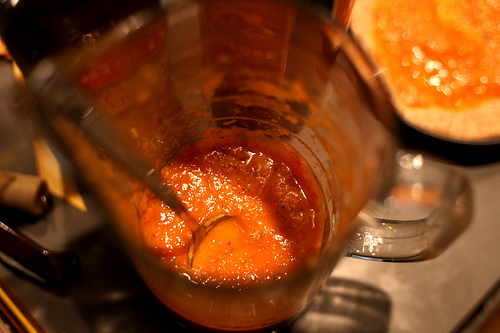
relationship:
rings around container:
[127, 81, 347, 293] [55, 22, 409, 323]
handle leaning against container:
[18, 57, 215, 232] [38, 24, 352, 324]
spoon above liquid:
[62, 105, 244, 262] [165, 153, 306, 263]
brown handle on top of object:
[1, 170, 48, 215] [2, 193, 111, 316]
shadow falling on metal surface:
[294, 279, 390, 331] [292, 146, 497, 331]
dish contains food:
[134, 89, 365, 257] [132, 148, 312, 266]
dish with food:
[134, 89, 365, 257] [132, 148, 312, 266]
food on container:
[361, 3, 499, 128] [44, 30, 462, 315]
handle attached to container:
[342, 148, 475, 265] [18, 2, 436, 328]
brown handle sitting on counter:
[1, 170, 48, 215] [19, 179, 487, 331]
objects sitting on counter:
[40, 137, 82, 208] [19, 179, 487, 331]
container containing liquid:
[22, 0, 475, 333] [113, 133, 328, 303]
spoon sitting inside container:
[40, 76, 237, 268] [22, 0, 475, 333]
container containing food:
[22, 0, 475, 333] [132, 137, 328, 288]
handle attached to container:
[342, 147, 477, 266] [22, 0, 475, 333]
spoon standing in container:
[40, 76, 237, 268] [22, 0, 475, 333]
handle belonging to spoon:
[18, 57, 207, 234] [40, 76, 237, 268]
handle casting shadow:
[342, 148, 475, 265] [288, 275, 392, 331]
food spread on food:
[347, 0, 499, 140] [350, 0, 484, 144]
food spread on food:
[347, 0, 499, 140] [347, 0, 499, 140]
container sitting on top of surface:
[22, 0, 475, 333] [2, 146, 483, 329]